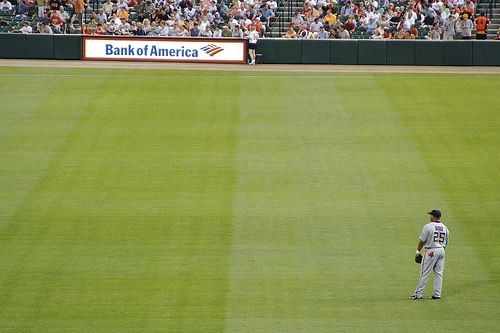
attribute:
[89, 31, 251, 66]
banner — white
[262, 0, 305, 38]
stairs — grey, green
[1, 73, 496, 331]
baseball field — grassy, green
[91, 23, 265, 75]
advertisement — red, white, blue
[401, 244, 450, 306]
pants — gray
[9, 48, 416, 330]
field — green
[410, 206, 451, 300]
player — standing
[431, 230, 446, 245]
number — black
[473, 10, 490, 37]
fan — crowd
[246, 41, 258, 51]
shorts — black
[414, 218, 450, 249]
jersey — gray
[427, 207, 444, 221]
hat — black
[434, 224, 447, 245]
writting — red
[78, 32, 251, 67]
sign — white, square, long